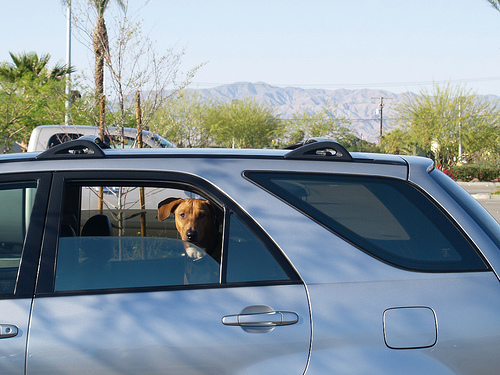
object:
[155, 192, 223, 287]
dog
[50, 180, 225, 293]
window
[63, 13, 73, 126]
pole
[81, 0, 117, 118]
tree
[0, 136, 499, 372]
car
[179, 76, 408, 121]
mountain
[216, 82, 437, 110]
distance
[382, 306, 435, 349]
gas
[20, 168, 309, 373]
door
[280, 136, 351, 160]
rack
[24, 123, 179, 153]
suv